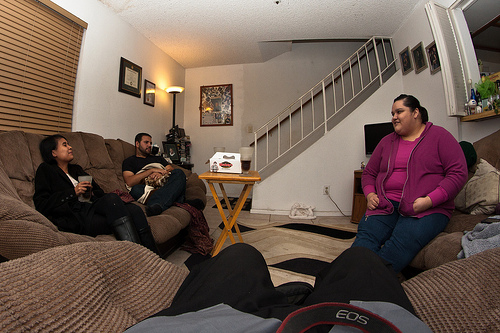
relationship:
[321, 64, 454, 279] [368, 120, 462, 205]
woman wearing shirt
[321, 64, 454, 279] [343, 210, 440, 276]
woman wearing jeans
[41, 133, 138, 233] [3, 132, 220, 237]
person on couch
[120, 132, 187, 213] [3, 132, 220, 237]
man on couch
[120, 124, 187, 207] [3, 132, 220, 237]
man on couch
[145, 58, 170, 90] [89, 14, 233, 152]
reflection on wall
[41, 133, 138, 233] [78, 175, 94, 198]
person holding cup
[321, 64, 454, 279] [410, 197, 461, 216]
woman has hand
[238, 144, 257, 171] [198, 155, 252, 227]
glass on table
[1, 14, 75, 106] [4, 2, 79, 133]
curtain on window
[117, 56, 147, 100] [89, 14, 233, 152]
picture on wall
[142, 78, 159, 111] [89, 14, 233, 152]
picture on wall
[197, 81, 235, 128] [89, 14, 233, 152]
picture on wall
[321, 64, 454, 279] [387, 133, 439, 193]
woman wearing purple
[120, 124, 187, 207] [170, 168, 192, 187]
man has knees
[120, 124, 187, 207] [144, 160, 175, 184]
man holding baby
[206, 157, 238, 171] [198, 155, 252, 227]
food on table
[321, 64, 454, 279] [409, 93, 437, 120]
woman has pony tail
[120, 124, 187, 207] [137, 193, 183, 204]
man wearing jeans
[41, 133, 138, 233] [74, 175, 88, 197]
woman has cup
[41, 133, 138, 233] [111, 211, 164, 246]
person wearing boots